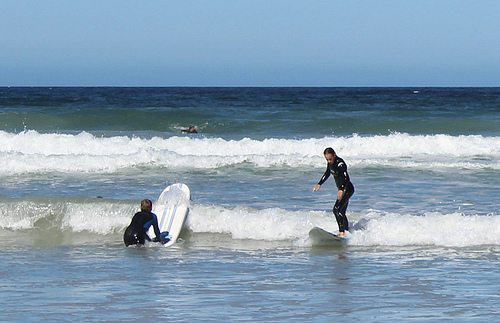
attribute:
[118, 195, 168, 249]
man — surfing, wet, heading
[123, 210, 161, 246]
wet suit — black, blue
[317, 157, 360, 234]
wet suit — shiny, black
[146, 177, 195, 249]
surfboard — white, facing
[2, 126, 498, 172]
wave — crashing, in, coming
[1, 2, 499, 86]
sky — blue, cloudless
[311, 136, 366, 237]
surfer — standing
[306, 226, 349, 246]
surfboard — white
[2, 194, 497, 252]
wave — coming, ridden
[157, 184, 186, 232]
stripes — blue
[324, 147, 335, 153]
hair — dark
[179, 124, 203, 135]
surfer — paddling, far out